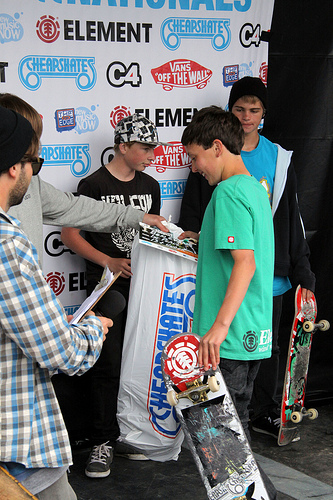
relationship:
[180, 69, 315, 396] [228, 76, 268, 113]
boy wearing skull cap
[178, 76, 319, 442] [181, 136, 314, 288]
boy wearing shirt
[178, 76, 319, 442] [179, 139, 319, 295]
boy wearing sweatshirt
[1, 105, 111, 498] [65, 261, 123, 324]
man with clipboard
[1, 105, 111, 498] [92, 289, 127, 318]
man with microphone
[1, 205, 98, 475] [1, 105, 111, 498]
shirt on man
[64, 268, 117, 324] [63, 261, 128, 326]
paper on clipboard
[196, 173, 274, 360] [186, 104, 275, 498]
green shirt on boy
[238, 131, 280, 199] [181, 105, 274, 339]
shirt on person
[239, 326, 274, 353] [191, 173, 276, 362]
writing on green shirt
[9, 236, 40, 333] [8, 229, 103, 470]
plaid on shirt